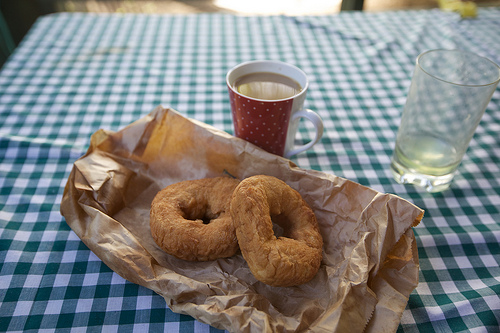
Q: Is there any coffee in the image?
A: Yes, there is coffee.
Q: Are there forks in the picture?
A: No, there are no forks.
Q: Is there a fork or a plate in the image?
A: No, there are no forks or plates.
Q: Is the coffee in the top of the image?
A: Yes, the coffee is in the top of the image.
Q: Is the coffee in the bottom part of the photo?
A: No, the coffee is in the top of the image.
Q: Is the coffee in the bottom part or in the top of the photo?
A: The coffee is in the top of the image.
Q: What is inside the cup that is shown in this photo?
A: The coffee is inside the cup.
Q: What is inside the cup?
A: The coffee is inside the cup.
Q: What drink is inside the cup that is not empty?
A: The drink is coffee.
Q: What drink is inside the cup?
A: The drink is coffee.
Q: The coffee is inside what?
A: The coffee is inside the cup.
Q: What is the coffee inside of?
A: The coffee is inside the cup.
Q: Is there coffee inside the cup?
A: Yes, there is coffee inside the cup.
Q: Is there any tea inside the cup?
A: No, there is coffee inside the cup.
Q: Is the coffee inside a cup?
A: Yes, the coffee is inside a cup.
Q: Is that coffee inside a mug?
A: No, the coffee is inside a cup.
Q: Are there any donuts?
A: Yes, there is a donut.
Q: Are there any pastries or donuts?
A: Yes, there is a donut.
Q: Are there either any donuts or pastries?
A: Yes, there is a donut.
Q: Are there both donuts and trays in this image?
A: No, there is a donut but no trays.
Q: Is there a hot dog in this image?
A: No, there are no hot dogs.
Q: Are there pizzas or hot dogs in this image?
A: No, there are no hot dogs or pizzas.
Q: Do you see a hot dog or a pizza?
A: No, there are no hot dogs or pizzas.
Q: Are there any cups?
A: Yes, there is a cup.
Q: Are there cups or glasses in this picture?
A: Yes, there is a cup.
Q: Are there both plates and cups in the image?
A: No, there is a cup but no plates.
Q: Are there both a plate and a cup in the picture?
A: No, there is a cup but no plates.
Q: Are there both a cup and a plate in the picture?
A: No, there is a cup but no plates.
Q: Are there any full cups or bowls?
A: Yes, there is a full cup.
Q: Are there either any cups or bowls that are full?
A: Yes, the cup is full.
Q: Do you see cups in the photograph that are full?
A: Yes, there is a full cup.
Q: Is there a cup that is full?
A: Yes, there is a cup that is full.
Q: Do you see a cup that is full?
A: Yes, there is a cup that is full.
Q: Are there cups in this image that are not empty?
A: Yes, there is an full cup.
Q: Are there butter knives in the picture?
A: No, there are no butter knives.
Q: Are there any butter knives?
A: No, there are no butter knives.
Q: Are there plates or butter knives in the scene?
A: No, there are no butter knives or plates.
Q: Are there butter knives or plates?
A: No, there are no butter knives or plates.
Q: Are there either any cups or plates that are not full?
A: No, there is a cup but it is full.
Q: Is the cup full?
A: Yes, the cup is full.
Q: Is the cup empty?
A: No, the cup is full.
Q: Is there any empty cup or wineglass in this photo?
A: No, there is a cup but it is full.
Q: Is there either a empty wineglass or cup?
A: No, there is a cup but it is full.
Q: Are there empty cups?
A: No, there is a cup but it is full.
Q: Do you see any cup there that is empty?
A: No, there is a cup but it is full.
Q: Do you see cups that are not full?
A: No, there is a cup but it is full.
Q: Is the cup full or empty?
A: The cup is full.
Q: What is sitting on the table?
A: The cup is sitting on the table.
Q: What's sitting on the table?
A: The cup is sitting on the table.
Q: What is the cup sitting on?
A: The cup is sitting on the table.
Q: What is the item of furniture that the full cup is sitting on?
A: The piece of furniture is a table.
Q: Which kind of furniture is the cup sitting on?
A: The cup is sitting on the table.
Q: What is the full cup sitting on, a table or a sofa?
A: The cup is sitting on a table.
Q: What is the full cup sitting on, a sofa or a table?
A: The cup is sitting on a table.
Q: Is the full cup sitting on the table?
A: Yes, the cup is sitting on the table.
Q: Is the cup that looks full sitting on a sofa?
A: No, the cup is sitting on the table.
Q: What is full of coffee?
A: The cup is full of coffee.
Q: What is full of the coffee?
A: The cup is full of coffee.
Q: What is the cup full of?
A: The cup is full of coffee.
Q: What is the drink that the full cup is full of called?
A: The drink is coffee.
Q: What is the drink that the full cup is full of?
A: The drink is coffee.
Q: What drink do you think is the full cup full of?
A: The cup is full of coffee.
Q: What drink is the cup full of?
A: The cup is full of coffee.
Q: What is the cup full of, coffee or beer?
A: The cup is full of coffee.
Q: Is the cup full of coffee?
A: Yes, the cup is full of coffee.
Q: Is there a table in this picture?
A: Yes, there is a table.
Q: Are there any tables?
A: Yes, there is a table.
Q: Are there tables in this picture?
A: Yes, there is a table.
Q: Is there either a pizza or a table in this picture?
A: Yes, there is a table.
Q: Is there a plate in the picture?
A: No, there are no plates.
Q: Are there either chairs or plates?
A: No, there are no plates or chairs.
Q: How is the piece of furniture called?
A: The piece of furniture is a table.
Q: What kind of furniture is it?
A: The piece of furniture is a table.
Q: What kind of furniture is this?
A: This is a table.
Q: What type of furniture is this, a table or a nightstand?
A: This is a table.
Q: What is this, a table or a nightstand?
A: This is a table.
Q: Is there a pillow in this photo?
A: No, there are no pillows.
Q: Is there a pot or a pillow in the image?
A: No, there are no pillows or pots.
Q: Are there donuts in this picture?
A: Yes, there is a donut.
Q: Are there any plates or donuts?
A: Yes, there is a donut.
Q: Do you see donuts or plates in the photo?
A: Yes, there is a donut.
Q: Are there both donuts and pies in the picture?
A: No, there is a donut but no pies.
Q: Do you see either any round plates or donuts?
A: Yes, there is a round donut.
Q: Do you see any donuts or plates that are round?
A: Yes, the donut is round.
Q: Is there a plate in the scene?
A: No, there are no plates.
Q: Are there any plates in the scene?
A: No, there are no plates.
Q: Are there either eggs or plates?
A: No, there are no plates or eggs.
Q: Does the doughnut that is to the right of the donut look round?
A: Yes, the donut is round.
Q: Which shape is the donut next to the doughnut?
A: The donut is round.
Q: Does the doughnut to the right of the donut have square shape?
A: No, the donut is round.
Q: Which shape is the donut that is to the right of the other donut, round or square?
A: The donut is round.